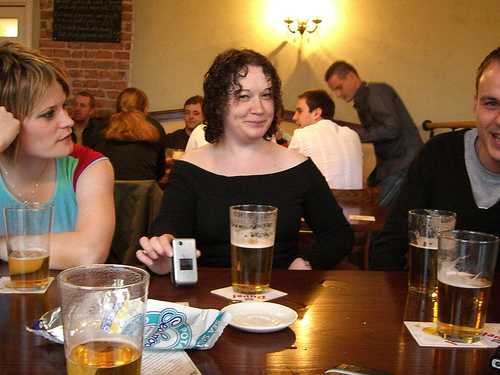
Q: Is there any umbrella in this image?
A: No, there are no umbrellas.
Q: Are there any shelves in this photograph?
A: No, there are no shelves.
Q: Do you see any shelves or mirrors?
A: No, there are no shelves or mirrors.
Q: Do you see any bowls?
A: No, there are no bowls.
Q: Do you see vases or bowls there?
A: No, there are no bowls or vases.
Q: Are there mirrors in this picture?
A: No, there are no mirrors.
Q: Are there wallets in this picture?
A: No, there are no wallets.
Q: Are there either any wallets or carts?
A: No, there are no wallets or carts.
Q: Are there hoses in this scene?
A: No, there are no hoses.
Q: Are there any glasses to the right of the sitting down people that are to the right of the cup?
A: Yes, there are glasses to the right of the people.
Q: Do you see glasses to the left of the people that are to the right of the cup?
A: No, the glasses are to the right of the people.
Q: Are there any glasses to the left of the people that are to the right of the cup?
A: No, the glasses are to the right of the people.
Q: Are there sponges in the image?
A: No, there are no sponges.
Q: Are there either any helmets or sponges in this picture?
A: No, there are no sponges or helmets.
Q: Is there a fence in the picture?
A: No, there are no fences.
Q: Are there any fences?
A: No, there are no fences.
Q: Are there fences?
A: No, there are no fences.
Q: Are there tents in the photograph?
A: No, there are no tents.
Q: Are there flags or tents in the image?
A: No, there are no tents or flags.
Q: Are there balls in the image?
A: No, there are no balls.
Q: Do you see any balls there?
A: No, there are no balls.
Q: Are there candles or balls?
A: No, there are no balls or candles.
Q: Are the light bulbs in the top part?
A: Yes, the light bulbs are in the top of the image.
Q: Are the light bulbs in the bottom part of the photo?
A: No, the light bulbs are in the top of the image.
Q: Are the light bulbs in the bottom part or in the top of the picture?
A: The light bulbs are in the top of the image.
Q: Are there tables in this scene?
A: Yes, there is a table.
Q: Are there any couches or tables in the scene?
A: Yes, there is a table.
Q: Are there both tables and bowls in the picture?
A: No, there is a table but no bowls.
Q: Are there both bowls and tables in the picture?
A: No, there is a table but no bowls.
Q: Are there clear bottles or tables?
A: Yes, there is a clear table.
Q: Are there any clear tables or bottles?
A: Yes, there is a clear table.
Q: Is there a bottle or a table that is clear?
A: Yes, the table is clear.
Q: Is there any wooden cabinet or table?
A: Yes, there is a wood table.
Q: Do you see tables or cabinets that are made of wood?
A: Yes, the table is made of wood.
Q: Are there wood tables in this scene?
A: Yes, there is a wood table.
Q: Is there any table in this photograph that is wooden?
A: Yes, there is a table that is wooden.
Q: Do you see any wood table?
A: Yes, there is a table that is made of wood.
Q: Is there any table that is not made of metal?
A: Yes, there is a table that is made of wood.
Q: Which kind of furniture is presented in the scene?
A: The furniture is a table.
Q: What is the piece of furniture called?
A: The piece of furniture is a table.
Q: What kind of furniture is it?
A: The piece of furniture is a table.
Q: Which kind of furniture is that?
A: That is a table.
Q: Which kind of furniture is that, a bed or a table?
A: That is a table.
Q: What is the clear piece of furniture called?
A: The piece of furniture is a table.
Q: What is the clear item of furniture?
A: The piece of furniture is a table.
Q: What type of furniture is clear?
A: The furniture is a table.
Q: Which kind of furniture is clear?
A: The furniture is a table.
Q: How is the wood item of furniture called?
A: The piece of furniture is a table.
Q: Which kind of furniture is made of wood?
A: The furniture is a table.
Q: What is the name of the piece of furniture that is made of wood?
A: The piece of furniture is a table.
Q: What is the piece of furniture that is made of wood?
A: The piece of furniture is a table.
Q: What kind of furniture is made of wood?
A: The furniture is a table.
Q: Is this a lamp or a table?
A: This is a table.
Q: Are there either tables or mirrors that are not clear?
A: No, there is a table but it is clear.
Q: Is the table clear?
A: Yes, the table is clear.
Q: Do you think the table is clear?
A: Yes, the table is clear.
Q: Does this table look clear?
A: Yes, the table is clear.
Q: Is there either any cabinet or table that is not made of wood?
A: No, there is a table but it is made of wood.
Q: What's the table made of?
A: The table is made of wood.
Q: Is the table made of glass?
A: No, the table is made of wood.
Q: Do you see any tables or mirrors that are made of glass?
A: No, there is a table but it is made of wood.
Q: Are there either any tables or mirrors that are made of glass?
A: No, there is a table but it is made of wood.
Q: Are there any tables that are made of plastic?
A: No, there is a table but it is made of wood.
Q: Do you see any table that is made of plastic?
A: No, there is a table but it is made of wood.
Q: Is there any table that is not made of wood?
A: No, there is a table but it is made of wood.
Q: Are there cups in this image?
A: Yes, there is a cup.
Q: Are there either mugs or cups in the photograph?
A: Yes, there is a cup.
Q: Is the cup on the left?
A: Yes, the cup is on the left of the image.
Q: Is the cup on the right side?
A: No, the cup is on the left of the image.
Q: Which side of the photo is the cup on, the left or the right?
A: The cup is on the left of the image.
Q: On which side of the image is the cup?
A: The cup is on the left of the image.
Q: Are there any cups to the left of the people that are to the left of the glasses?
A: Yes, there is a cup to the left of the people.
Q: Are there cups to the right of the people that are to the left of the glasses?
A: No, the cup is to the left of the people.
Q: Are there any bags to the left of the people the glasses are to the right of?
A: No, there is a cup to the left of the people.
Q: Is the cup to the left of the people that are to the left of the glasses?
A: Yes, the cup is to the left of the people.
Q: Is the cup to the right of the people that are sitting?
A: No, the cup is to the left of the people.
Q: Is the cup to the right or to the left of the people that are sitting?
A: The cup is to the left of the people.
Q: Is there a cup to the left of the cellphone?
A: Yes, there is a cup to the left of the cellphone.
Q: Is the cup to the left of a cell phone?
A: Yes, the cup is to the left of a cell phone.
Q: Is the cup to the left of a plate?
A: No, the cup is to the left of a cell phone.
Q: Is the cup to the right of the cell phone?
A: No, the cup is to the left of the cell phone.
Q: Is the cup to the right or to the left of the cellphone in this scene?
A: The cup is to the left of the cellphone.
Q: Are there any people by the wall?
A: Yes, there are people by the wall.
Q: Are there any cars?
A: No, there are no cars.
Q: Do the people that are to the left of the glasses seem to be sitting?
A: Yes, the people are sitting.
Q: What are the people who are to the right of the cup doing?
A: The people are sitting.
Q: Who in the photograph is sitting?
A: The people are sitting.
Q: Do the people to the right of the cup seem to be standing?
A: No, the people are sitting.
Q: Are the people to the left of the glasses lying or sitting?
A: The people are sitting.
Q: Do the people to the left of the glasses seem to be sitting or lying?
A: The people are sitting.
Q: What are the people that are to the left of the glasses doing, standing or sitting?
A: The people are sitting.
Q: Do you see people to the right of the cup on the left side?
A: Yes, there are people to the right of the cup.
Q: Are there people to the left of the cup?
A: No, the people are to the right of the cup.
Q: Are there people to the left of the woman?
A: No, the people are to the right of the woman.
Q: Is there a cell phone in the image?
A: Yes, there is a cell phone.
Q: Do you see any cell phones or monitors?
A: Yes, there is a cell phone.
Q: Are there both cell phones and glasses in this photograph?
A: Yes, there are both a cell phone and glasses.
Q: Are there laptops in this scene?
A: No, there are no laptops.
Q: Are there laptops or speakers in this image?
A: No, there are no laptops or speakers.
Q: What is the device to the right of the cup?
A: The device is a cell phone.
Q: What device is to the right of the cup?
A: The device is a cell phone.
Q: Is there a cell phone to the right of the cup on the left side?
A: Yes, there is a cell phone to the right of the cup.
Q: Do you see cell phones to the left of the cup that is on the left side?
A: No, the cell phone is to the right of the cup.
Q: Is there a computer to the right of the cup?
A: No, there is a cell phone to the right of the cup.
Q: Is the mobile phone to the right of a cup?
A: Yes, the mobile phone is to the right of a cup.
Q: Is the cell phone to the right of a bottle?
A: No, the cell phone is to the right of a cup.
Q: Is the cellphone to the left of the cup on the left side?
A: No, the cellphone is to the right of the cup.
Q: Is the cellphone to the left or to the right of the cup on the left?
A: The cellphone is to the right of the cup.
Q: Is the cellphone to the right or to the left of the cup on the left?
A: The cellphone is to the right of the cup.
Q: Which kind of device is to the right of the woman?
A: The device is a cell phone.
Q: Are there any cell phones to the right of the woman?
A: Yes, there is a cell phone to the right of the woman.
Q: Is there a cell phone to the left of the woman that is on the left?
A: No, the cell phone is to the right of the woman.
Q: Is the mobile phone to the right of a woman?
A: Yes, the mobile phone is to the right of a woman.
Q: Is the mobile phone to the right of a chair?
A: No, the mobile phone is to the right of a woman.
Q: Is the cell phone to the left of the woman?
A: No, the cell phone is to the right of the woman.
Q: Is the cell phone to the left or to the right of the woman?
A: The cell phone is to the right of the woman.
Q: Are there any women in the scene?
A: Yes, there is a woman.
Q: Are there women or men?
A: Yes, there is a woman.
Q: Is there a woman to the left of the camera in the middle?
A: Yes, there is a woman to the left of the camera.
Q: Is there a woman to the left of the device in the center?
A: Yes, there is a woman to the left of the camera.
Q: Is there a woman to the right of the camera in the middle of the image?
A: No, the woman is to the left of the camera.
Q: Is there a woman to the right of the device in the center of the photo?
A: No, the woman is to the left of the camera.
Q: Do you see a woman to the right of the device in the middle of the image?
A: No, the woman is to the left of the camera.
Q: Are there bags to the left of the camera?
A: No, there is a woman to the left of the camera.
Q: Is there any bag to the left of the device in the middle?
A: No, there is a woman to the left of the camera.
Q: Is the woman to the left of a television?
A: No, the woman is to the left of a camera.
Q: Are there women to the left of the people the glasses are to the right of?
A: Yes, there is a woman to the left of the people.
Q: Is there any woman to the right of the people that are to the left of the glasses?
A: No, the woman is to the left of the people.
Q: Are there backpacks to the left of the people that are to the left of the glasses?
A: No, there is a woman to the left of the people.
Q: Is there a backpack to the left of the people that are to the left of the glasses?
A: No, there is a woman to the left of the people.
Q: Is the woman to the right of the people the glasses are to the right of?
A: No, the woman is to the left of the people.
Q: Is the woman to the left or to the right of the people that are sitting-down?
A: The woman is to the left of the people.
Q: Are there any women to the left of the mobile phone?
A: Yes, there is a woman to the left of the mobile phone.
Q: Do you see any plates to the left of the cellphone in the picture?
A: No, there is a woman to the left of the cellphone.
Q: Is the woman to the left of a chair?
A: No, the woman is to the left of the cell phone.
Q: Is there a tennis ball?
A: No, there are no tennis balls.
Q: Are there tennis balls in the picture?
A: No, there are no tennis balls.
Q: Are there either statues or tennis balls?
A: No, there are no tennis balls or statues.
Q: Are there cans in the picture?
A: No, there are no cans.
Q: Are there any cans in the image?
A: No, there are no cans.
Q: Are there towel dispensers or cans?
A: No, there are no cans or towel dispensers.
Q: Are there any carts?
A: No, there are no carts.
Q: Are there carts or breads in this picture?
A: No, there are no carts or breads.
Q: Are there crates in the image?
A: No, there are no crates.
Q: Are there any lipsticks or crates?
A: No, there are no crates or lipsticks.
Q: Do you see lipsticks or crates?
A: No, there are no crates or lipsticks.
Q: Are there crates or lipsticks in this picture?
A: No, there are no crates or lipsticks.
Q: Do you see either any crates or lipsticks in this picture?
A: No, there are no crates or lipsticks.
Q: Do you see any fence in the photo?
A: No, there are no fences.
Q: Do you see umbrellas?
A: No, there are no umbrellas.